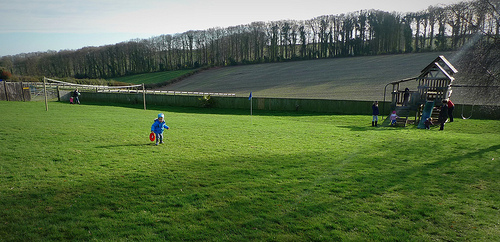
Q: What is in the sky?
A: Clouds.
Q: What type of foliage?
A: Trees.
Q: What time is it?
A: Afternoon.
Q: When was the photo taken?
A: During the daytime.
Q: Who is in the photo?
A: A person.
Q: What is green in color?
A: Grass.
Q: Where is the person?
A: On grass.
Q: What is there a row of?
A: Trees.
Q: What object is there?
A: A playhouse.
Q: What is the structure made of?
A: Wood.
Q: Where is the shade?
A: On the grass.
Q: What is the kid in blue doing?
A: Standing with a red object.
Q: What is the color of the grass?
A: Green.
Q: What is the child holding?
A: Freebee.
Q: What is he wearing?
A: Blue jacket.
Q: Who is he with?
A: Other kids.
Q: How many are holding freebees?
A: 1.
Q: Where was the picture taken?
A: In the field.